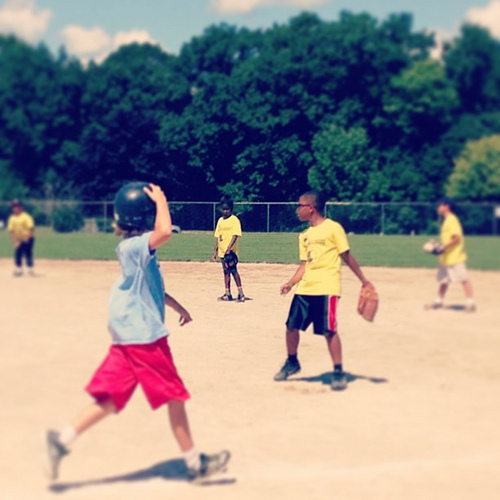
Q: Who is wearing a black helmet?
A: The child.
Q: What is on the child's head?
A: Black helmet.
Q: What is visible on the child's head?
A: Black helmet.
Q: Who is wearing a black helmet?
A: The child in red shorts.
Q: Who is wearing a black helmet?
A: The child in the gray shirt.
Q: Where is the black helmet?
A: On the child's head.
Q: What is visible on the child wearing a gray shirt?
A: Black helmet.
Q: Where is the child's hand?
A: Holding the black helmet.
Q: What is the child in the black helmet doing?
A: Playing baseball.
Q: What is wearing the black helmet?
A: The boy.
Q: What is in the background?
A: The fence.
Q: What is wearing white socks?
A: The boy.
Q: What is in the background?
A: The trees.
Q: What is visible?
A: The black helmet.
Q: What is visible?
A: The black helmet.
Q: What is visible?
A: The black helmet.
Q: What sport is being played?
A: Baseball.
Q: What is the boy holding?
A: Helmet.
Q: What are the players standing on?
A: Dirt.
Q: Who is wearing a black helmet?
A: The boy with red shorts.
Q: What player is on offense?
A: The boy in red shorts.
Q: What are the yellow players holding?
A: Glove.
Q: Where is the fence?
A: Behind the grass.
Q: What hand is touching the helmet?
A: Right.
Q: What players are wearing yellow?
A: Defense.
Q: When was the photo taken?
A: Daytime.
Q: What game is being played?
A: Baseball.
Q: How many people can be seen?
A: Five.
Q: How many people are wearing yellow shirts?
A: Four.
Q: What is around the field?
A: Fence.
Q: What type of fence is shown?
A: Metal.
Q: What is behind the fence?
A: Trees.